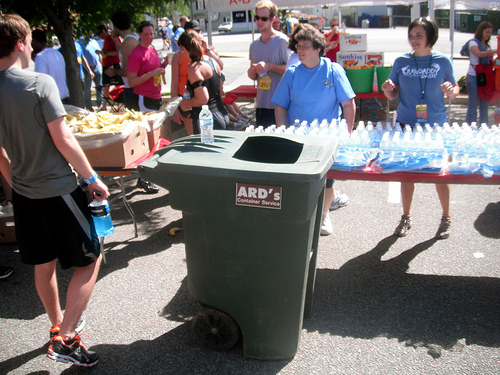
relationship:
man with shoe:
[1, 14, 113, 367] [46, 336, 100, 367]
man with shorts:
[1, 14, 113, 367] [11, 192, 99, 268]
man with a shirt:
[1, 14, 113, 367] [1, 69, 81, 200]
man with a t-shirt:
[1, 14, 113, 367] [1, 69, 81, 200]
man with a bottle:
[1, 14, 113, 367] [89, 192, 115, 239]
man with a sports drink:
[1, 14, 113, 367] [89, 192, 115, 239]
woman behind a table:
[380, 17, 459, 124] [339, 121, 499, 186]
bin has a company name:
[127, 129, 337, 360] [234, 182, 282, 212]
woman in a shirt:
[380, 17, 459, 124] [390, 55, 456, 125]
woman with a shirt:
[126, 22, 165, 110] [128, 44, 164, 100]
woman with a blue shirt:
[380, 17, 459, 124] [390, 55, 456, 125]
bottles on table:
[337, 117, 499, 171] [339, 121, 499, 186]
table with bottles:
[339, 121, 499, 186] [337, 117, 499, 171]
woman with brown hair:
[176, 30, 229, 131] [176, 29, 205, 62]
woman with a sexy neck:
[273, 23, 356, 122] [296, 54, 323, 68]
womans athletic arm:
[176, 30, 229, 131] [177, 65, 208, 118]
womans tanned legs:
[380, 17, 459, 124] [396, 180, 450, 241]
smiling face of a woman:
[408, 24, 427, 50] [380, 17, 459, 124]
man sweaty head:
[1, 14, 113, 367] [0, 14, 33, 67]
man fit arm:
[1, 14, 113, 367] [42, 75, 99, 185]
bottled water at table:
[337, 117, 499, 171] [339, 121, 499, 186]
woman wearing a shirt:
[380, 17, 459, 124] [390, 55, 456, 125]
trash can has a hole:
[127, 129, 337, 360] [232, 135, 304, 164]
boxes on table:
[80, 122, 149, 167] [96, 166, 143, 238]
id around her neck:
[411, 53, 432, 124] [412, 48, 434, 63]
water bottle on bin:
[199, 100, 217, 147] [127, 129, 337, 360]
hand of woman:
[380, 77, 399, 96] [381, 16, 461, 242]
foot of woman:
[433, 214, 452, 246] [381, 16, 461, 242]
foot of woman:
[391, 211, 411, 237] [381, 16, 461, 242]